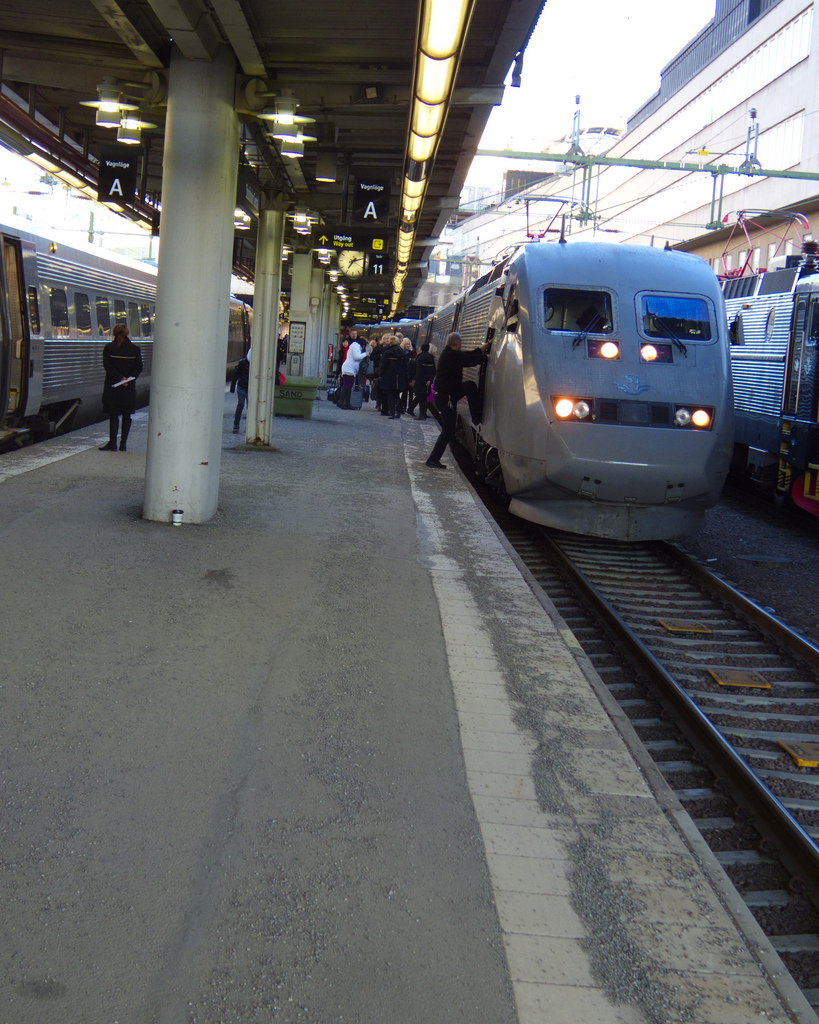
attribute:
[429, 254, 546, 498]
door — open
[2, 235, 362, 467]
train — subway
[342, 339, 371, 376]
sweater — white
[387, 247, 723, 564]
train — long, silver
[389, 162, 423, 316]
light — long, yellow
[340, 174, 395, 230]
sign — black, white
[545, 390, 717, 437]
headlights — yellow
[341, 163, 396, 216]
sign — black, white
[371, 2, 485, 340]
light — yellow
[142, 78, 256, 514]
post — white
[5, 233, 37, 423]
door — open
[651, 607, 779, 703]
blocks — yellow